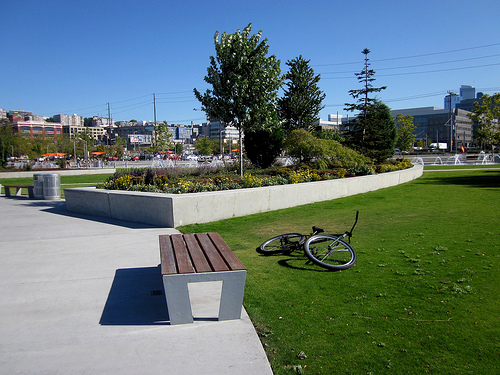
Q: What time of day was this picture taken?
A: Day time.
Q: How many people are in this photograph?
A: Zero.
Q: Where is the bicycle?
A: On the grass.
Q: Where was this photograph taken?
A: In a park.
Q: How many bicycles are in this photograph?
A: One.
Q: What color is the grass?
A: Green.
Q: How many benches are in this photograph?
A: Two.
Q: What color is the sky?
A: Blue.